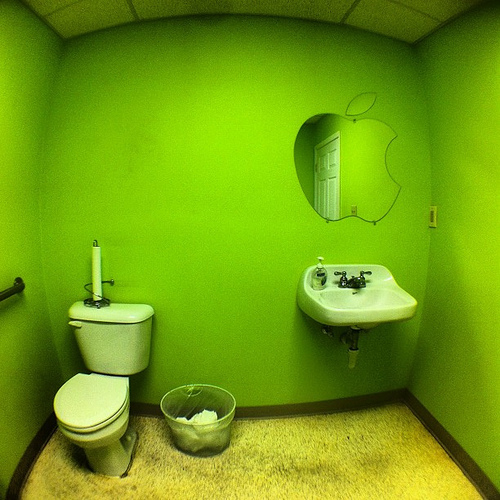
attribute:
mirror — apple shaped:
[281, 81, 407, 234]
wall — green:
[61, 20, 414, 405]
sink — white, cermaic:
[283, 245, 440, 376]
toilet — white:
[39, 283, 163, 483]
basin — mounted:
[293, 250, 424, 373]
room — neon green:
[1, 0, 497, 490]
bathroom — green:
[1, 4, 499, 483]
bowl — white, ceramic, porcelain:
[55, 369, 149, 483]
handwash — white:
[306, 252, 333, 296]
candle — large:
[83, 233, 119, 317]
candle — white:
[78, 227, 118, 312]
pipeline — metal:
[0, 268, 31, 306]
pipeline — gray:
[310, 319, 390, 385]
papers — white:
[166, 402, 228, 453]